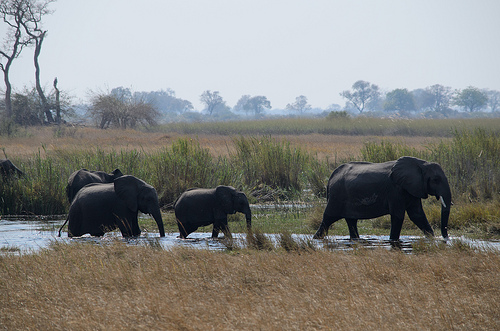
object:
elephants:
[57, 154, 457, 249]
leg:
[405, 193, 437, 245]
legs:
[309, 211, 338, 241]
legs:
[308, 213, 367, 243]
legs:
[379, 195, 438, 245]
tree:
[198, 88, 225, 121]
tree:
[233, 94, 272, 120]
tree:
[285, 94, 314, 117]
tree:
[338, 79, 380, 116]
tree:
[383, 88, 416, 115]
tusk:
[433, 193, 464, 212]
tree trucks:
[0, 31, 80, 131]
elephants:
[53, 166, 165, 244]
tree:
[78, 84, 165, 132]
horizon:
[0, 98, 499, 128]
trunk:
[432, 179, 454, 246]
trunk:
[146, 183, 168, 249]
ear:
[389, 156, 432, 200]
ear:
[213, 184, 235, 216]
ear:
[113, 173, 139, 214]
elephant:
[313, 156, 456, 247]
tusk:
[435, 194, 450, 209]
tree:
[483, 89, 499, 115]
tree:
[453, 86, 487, 114]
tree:
[410, 84, 446, 114]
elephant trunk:
[435, 182, 456, 248]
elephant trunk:
[240, 201, 257, 237]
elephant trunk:
[151, 206, 168, 240]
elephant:
[167, 176, 271, 255]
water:
[346, 228, 398, 256]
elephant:
[54, 172, 170, 242]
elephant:
[62, 165, 125, 204]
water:
[1, 210, 499, 264]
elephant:
[39, 149, 482, 269]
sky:
[0, 7, 495, 126]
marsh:
[0, 118, 500, 323]